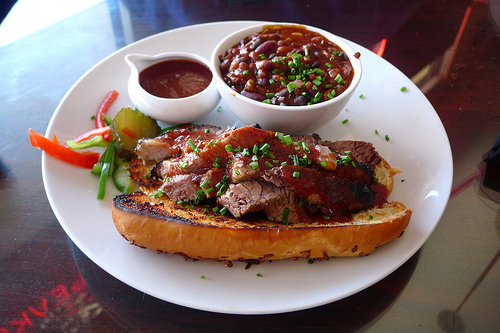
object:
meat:
[147, 133, 352, 217]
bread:
[111, 199, 414, 263]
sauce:
[266, 151, 329, 200]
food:
[117, 35, 380, 256]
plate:
[41, 19, 455, 317]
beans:
[238, 35, 301, 91]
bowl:
[255, 94, 346, 136]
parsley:
[229, 141, 284, 173]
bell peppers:
[48, 129, 119, 203]